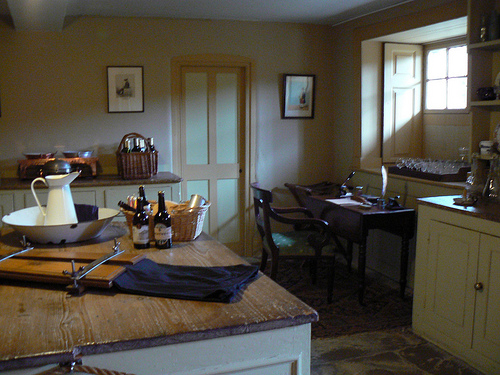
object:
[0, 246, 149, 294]
cutting board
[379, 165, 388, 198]
quill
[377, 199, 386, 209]
bottle of ink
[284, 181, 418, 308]
desk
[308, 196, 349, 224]
wood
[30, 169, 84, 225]
water pitcher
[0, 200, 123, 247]
basin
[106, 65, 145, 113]
photograph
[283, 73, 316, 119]
frame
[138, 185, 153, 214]
wine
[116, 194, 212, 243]
basket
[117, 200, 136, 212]
wine bottles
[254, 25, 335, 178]
wall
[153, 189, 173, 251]
wine bottles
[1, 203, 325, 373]
table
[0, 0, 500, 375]
kitchen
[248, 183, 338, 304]
chair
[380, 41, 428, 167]
window shutter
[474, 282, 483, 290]
knob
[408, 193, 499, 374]
cabinet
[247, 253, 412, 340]
rug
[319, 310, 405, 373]
floor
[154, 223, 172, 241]
white labels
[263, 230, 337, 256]
cushion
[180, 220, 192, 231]
brown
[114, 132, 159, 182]
basket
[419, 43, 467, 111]
window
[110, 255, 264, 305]
table cloth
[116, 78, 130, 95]
person sitting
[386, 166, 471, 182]
tray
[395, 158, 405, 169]
glasses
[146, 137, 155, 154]
wine bottles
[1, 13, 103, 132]
wall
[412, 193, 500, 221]
couter